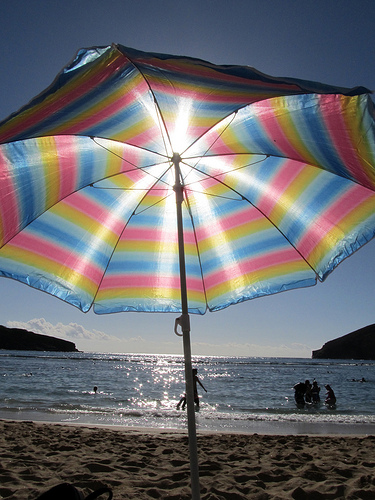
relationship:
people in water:
[323, 385, 337, 417] [0, 358, 372, 430]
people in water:
[311, 381, 324, 409] [0, 358, 372, 430]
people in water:
[302, 377, 313, 402] [0, 358, 372, 430]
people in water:
[294, 381, 306, 416] [0, 358, 372, 430]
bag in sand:
[41, 475, 115, 500] [0, 423, 372, 499]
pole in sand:
[173, 158, 198, 500] [0, 423, 372, 499]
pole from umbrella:
[173, 158, 198, 500] [4, 43, 375, 500]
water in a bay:
[0, 358, 372, 430] [4, 347, 373, 498]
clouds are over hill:
[14, 319, 157, 352] [6, 325, 79, 353]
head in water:
[86, 386, 100, 397] [0, 358, 372, 430]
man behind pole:
[187, 364, 206, 411] [173, 158, 198, 500]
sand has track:
[0, 423, 372, 499] [0, 415, 374, 497]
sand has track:
[0, 423, 372, 499] [295, 461, 327, 485]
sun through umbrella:
[79, 90, 329, 300] [4, 43, 375, 500]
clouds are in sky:
[14, 319, 157, 352] [0, 0, 371, 358]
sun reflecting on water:
[79, 90, 329, 300] [0, 358, 372, 430]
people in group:
[323, 385, 337, 417] [291, 374, 339, 415]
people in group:
[311, 381, 324, 409] [291, 374, 339, 415]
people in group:
[302, 377, 313, 402] [291, 374, 339, 415]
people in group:
[294, 381, 306, 416] [291, 374, 339, 415]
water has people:
[0, 358, 372, 430] [323, 385, 337, 417]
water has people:
[0, 358, 372, 430] [294, 381, 306, 416]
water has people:
[0, 358, 372, 430] [302, 377, 313, 402]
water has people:
[0, 358, 372, 430] [311, 381, 324, 409]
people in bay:
[323, 385, 337, 417] [4, 347, 373, 498]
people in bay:
[294, 381, 306, 416] [4, 347, 373, 498]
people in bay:
[302, 377, 313, 402] [4, 347, 373, 498]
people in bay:
[311, 381, 324, 409] [4, 347, 373, 498]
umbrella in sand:
[4, 43, 375, 500] [0, 423, 372, 499]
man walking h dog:
[187, 364, 206, 411] [173, 395, 200, 414]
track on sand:
[0, 415, 374, 497] [0, 423, 372, 499]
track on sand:
[295, 461, 327, 485] [0, 423, 372, 499]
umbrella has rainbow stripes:
[4, 43, 375, 500] [123, 127, 225, 197]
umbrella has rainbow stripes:
[4, 43, 375, 500] [111, 112, 246, 212]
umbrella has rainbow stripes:
[4, 43, 375, 500] [76, 96, 277, 225]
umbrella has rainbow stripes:
[4, 43, 375, 500] [37, 72, 321, 264]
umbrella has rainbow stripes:
[4, 43, 375, 500] [6, 61, 352, 280]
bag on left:
[41, 475, 115, 500] [10, 421, 149, 499]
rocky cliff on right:
[297, 475, 362, 499] [292, 446, 374, 496]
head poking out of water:
[86, 386, 100, 397] [0, 358, 372, 430]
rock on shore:
[118, 411, 141, 421] [8, 407, 374, 442]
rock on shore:
[244, 411, 275, 432] [8, 407, 374, 442]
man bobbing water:
[187, 364, 206, 411] [0, 358, 372, 430]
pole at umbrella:
[173, 158, 198, 500] [4, 43, 375, 500]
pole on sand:
[173, 158, 198, 500] [0, 423, 372, 499]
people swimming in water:
[323, 385, 337, 417] [0, 358, 372, 430]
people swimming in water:
[294, 381, 306, 416] [0, 358, 372, 430]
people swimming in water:
[311, 381, 324, 409] [0, 358, 372, 430]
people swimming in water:
[302, 377, 313, 402] [0, 358, 372, 430]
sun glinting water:
[79, 90, 329, 300] [0, 358, 372, 430]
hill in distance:
[6, 325, 79, 353] [2, 279, 369, 370]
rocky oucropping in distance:
[306, 322, 375, 360] [2, 279, 369, 370]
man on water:
[187, 364, 206, 411] [0, 358, 372, 430]